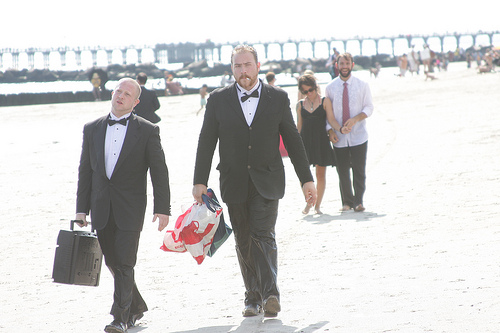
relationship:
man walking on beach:
[92, 78, 162, 331] [11, 100, 480, 330]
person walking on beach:
[296, 70, 341, 215] [0, 57, 497, 329]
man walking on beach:
[218, 49, 288, 318] [389, 85, 495, 322]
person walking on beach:
[409, 37, 437, 80] [11, 100, 480, 330]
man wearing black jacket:
[92, 78, 162, 331] [75, 114, 171, 216]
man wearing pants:
[92, 78, 162, 331] [95, 196, 142, 318]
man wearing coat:
[218, 49, 288, 318] [188, 75, 309, 293]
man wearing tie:
[218, 49, 288, 318] [233, 84, 263, 104]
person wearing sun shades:
[296, 70, 341, 215] [297, 84, 318, 96]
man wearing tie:
[327, 52, 378, 221] [339, 78, 352, 127]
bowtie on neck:
[238, 90, 260, 101] [234, 77, 261, 94]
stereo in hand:
[47, 217, 106, 287] [69, 206, 96, 236]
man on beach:
[92, 78, 162, 331] [11, 100, 480, 330]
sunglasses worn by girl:
[297, 82, 319, 95] [292, 71, 350, 218]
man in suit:
[92, 78, 162, 331] [75, 112, 172, 317]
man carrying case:
[92, 78, 162, 331] [49, 218, 102, 285]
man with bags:
[218, 49, 288, 318] [149, 173, 239, 271]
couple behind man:
[288, 46, 378, 233] [218, 49, 288, 318]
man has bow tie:
[218, 49, 288, 318] [241, 88, 263, 105]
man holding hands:
[327, 52, 378, 221] [322, 116, 342, 146]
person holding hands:
[296, 70, 341, 215] [322, 116, 342, 146]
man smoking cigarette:
[218, 49, 288, 318] [233, 65, 257, 92]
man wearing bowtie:
[218, 49, 288, 318] [220, 74, 282, 114]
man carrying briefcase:
[92, 78, 162, 331] [54, 219, 101, 285]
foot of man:
[110, 315, 121, 330] [83, 75, 177, 281]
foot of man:
[295, 187, 327, 214] [83, 75, 177, 281]